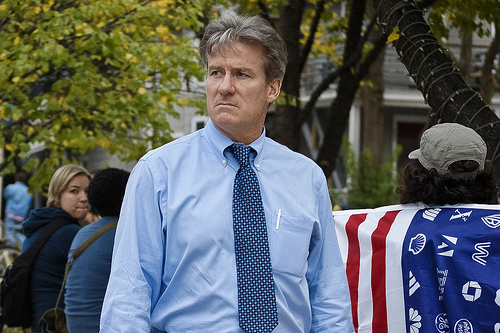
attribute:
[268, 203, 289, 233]
pen — part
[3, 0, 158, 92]
leaves — green, yellow.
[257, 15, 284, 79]
hair — Part , brown., man's 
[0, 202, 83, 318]
woman — dark blue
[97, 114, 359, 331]
dress shirt — blue 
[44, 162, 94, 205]
hair — blonde 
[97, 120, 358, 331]
shirt — part, long sleeved light blue, blue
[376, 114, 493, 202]
man — older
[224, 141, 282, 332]
tie — edge 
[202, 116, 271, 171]
collar — man's 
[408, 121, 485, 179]
cap — gray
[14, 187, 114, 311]
bag — black 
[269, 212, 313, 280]
pocket — part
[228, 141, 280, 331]
tie — long, dotted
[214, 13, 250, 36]
hair — grey, Part 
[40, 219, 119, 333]
bag — greenish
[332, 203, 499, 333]
fabric — red, white, blue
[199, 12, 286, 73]
hair — grey